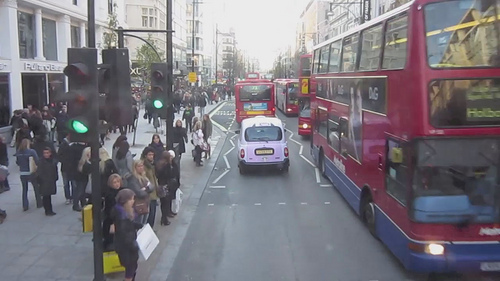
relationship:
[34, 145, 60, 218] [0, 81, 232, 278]
pedestrian on sidewalk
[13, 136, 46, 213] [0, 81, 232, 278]
pedestrian on sidewalk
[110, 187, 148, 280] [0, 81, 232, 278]
pedestrian on sidewalk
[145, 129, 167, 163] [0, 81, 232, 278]
pedestrian on sidewalk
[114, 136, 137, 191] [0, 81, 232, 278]
pedestrian on sidewalk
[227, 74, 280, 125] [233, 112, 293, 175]
bus in front of car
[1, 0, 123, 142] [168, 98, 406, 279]
building along street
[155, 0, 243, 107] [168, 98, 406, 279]
building along street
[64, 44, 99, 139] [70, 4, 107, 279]
signal on pole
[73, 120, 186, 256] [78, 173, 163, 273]
person hold bag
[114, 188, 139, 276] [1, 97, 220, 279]
people on sidewalk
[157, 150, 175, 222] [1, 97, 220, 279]
people on sidewalk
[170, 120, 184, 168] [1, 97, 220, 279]
people on sidewalk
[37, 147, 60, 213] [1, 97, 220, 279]
people on sidewalk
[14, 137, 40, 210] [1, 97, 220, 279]
person on sidewalk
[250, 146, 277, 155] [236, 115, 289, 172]
licence plate on car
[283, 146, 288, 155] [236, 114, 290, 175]
tail lights on car car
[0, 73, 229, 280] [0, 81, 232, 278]
people in sidewalk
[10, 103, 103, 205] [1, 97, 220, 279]
people in sidewalk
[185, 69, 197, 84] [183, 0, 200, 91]
sign on pole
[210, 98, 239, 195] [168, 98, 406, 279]
marking on street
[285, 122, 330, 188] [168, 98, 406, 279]
marking on street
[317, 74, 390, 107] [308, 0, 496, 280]
ad on side of bus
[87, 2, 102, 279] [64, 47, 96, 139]
pole has traffic light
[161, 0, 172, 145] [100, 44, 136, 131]
pole has traffic light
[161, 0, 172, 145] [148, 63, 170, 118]
pole has traffic light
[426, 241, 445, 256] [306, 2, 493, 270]
headlight on bus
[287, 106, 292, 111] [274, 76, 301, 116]
headlight on bus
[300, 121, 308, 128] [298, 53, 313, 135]
headlight on bus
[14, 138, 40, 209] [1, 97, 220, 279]
person walking on sidewalk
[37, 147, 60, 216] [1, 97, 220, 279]
people walking on sidewalk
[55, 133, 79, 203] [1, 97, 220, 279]
person walking on sidewalk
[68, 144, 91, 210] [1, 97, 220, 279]
person walking on sidewalk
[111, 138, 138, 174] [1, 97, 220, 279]
person walking on sidewalk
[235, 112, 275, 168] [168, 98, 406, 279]
vehicle on street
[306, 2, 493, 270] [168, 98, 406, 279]
bus on street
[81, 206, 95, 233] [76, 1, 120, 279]
bag attached to pole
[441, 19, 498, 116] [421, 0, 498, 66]
buildings reflected in window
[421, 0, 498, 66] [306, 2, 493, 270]
window on bus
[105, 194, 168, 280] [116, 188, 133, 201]
woman has hair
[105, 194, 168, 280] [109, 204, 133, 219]
woman wearing scarf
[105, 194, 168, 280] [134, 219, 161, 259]
woman carrying bag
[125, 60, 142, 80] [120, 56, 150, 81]
letters "xt" on sign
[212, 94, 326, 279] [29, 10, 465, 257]
street in city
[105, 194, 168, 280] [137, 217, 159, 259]
woman holding bag